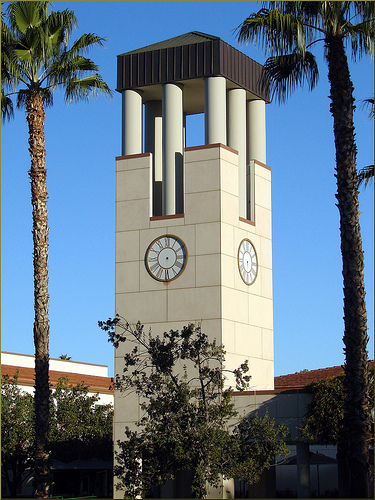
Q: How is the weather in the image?
A: It is clear.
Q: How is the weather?
A: It is clear.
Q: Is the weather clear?
A: Yes, it is clear.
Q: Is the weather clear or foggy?
A: It is clear.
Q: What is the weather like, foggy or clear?
A: It is clear.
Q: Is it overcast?
A: No, it is clear.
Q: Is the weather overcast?
A: No, it is clear.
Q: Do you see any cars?
A: No, there are no cars.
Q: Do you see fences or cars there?
A: No, there are no cars or fences.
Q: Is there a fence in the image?
A: No, there are no fences.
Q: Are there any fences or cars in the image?
A: No, there are no fences or cars.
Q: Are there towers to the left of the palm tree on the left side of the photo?
A: No, the tower is to the right of the palm.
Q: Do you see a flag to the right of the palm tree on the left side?
A: No, there is a tower to the right of the palm tree.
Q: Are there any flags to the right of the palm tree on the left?
A: No, there is a tower to the right of the palm tree.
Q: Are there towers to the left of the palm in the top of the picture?
A: Yes, there is a tower to the left of the palm.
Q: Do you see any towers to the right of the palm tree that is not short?
A: No, the tower is to the left of the palm.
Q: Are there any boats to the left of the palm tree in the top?
A: No, there is a tower to the left of the palm tree.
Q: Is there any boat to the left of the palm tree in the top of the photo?
A: No, there is a tower to the left of the palm tree.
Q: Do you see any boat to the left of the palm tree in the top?
A: No, there is a tower to the left of the palm tree.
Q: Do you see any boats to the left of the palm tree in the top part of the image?
A: No, there is a tower to the left of the palm tree.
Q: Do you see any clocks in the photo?
A: Yes, there is a clock.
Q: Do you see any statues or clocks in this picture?
A: Yes, there is a clock.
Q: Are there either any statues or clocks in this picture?
A: Yes, there is a clock.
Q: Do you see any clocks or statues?
A: Yes, there is a clock.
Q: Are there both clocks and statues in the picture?
A: No, there is a clock but no statues.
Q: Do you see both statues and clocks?
A: No, there is a clock but no statues.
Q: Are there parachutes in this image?
A: No, there are no parachutes.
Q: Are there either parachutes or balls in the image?
A: No, there are no parachutes or balls.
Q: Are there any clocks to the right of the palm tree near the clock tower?
A: Yes, there is a clock to the right of the palm tree.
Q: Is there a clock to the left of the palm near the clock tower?
A: No, the clock is to the right of the palm.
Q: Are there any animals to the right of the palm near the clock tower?
A: No, there is a clock to the right of the palm tree.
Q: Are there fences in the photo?
A: No, there are no fences.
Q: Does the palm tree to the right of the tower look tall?
A: Yes, the palm is tall.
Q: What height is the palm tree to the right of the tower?
A: The palm tree is tall.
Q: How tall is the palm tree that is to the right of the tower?
A: The palm tree is tall.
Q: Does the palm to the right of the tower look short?
A: No, the palm is tall.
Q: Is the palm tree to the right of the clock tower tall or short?
A: The palm is tall.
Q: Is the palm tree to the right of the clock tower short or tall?
A: The palm is tall.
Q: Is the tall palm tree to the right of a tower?
A: Yes, the palm is to the right of a tower.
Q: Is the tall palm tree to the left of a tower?
A: No, the palm is to the right of a tower.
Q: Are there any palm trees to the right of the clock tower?
A: Yes, there is a palm tree to the right of the clock tower.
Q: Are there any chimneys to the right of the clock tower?
A: No, there is a palm tree to the right of the clock tower.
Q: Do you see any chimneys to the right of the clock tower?
A: No, there is a palm tree to the right of the clock tower.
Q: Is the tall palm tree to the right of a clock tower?
A: Yes, the palm is to the right of a clock tower.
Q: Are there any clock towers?
A: Yes, there is a clock tower.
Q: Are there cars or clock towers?
A: Yes, there is a clock tower.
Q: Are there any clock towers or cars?
A: Yes, there is a clock tower.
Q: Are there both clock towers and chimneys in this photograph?
A: No, there is a clock tower but no chimneys.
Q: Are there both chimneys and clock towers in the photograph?
A: No, there is a clock tower but no chimneys.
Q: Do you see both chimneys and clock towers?
A: No, there is a clock tower but no chimneys.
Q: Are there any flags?
A: No, there are no flags.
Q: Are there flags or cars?
A: No, there are no flags or cars.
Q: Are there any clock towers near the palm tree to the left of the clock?
A: Yes, there is a clock tower near the palm tree.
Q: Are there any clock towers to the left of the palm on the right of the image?
A: Yes, there is a clock tower to the left of the palm tree.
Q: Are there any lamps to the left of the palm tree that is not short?
A: No, there is a clock tower to the left of the palm tree.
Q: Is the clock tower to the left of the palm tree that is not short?
A: Yes, the clock tower is to the left of the palm tree.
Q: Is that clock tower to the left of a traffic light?
A: No, the clock tower is to the left of the palm tree.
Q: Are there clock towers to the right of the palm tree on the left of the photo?
A: Yes, there is a clock tower to the right of the palm.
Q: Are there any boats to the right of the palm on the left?
A: No, there is a clock tower to the right of the palm.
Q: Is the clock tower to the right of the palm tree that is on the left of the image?
A: Yes, the clock tower is to the right of the palm tree.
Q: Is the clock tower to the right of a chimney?
A: No, the clock tower is to the right of the palm tree.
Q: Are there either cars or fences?
A: No, there are no cars or fences.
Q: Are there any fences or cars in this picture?
A: No, there are no cars or fences.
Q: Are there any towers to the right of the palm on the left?
A: Yes, there is a tower to the right of the palm.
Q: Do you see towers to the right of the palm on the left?
A: Yes, there is a tower to the right of the palm.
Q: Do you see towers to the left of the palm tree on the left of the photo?
A: No, the tower is to the right of the palm tree.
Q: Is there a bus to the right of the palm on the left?
A: No, there is a tower to the right of the palm tree.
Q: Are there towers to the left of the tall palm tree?
A: Yes, there is a tower to the left of the palm.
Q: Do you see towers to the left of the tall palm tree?
A: Yes, there is a tower to the left of the palm.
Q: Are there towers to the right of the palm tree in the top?
A: No, the tower is to the left of the palm tree.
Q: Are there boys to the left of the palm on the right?
A: No, there is a tower to the left of the palm.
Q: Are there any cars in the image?
A: No, there are no cars.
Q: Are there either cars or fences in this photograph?
A: No, there are no cars or fences.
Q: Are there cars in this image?
A: No, there are no cars.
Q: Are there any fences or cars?
A: No, there are no cars or fences.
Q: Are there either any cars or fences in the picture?
A: No, there are no cars or fences.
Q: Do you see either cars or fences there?
A: No, there are no cars or fences.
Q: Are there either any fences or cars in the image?
A: No, there are no cars or fences.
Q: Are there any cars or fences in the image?
A: No, there are no cars or fences.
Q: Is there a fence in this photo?
A: No, there are no fences.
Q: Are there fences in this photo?
A: No, there are no fences.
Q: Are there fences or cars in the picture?
A: No, there are no fences or cars.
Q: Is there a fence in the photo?
A: No, there are no fences.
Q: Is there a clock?
A: Yes, there is a clock.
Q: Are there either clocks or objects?
A: Yes, there is a clock.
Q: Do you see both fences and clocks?
A: No, there is a clock but no fences.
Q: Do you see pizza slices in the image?
A: No, there are no pizza slices.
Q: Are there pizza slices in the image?
A: No, there are no pizza slices.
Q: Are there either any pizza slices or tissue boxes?
A: No, there are no pizza slices or tissue boxes.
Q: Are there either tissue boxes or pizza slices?
A: No, there are no pizza slices or tissue boxes.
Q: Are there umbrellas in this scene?
A: Yes, there is an umbrella.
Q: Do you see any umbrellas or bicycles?
A: Yes, there is an umbrella.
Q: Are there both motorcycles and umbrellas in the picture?
A: No, there is an umbrella but no motorcycles.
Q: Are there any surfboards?
A: No, there are no surfboards.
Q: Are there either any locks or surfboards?
A: No, there are no surfboards or locks.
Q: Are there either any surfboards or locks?
A: No, there are no surfboards or locks.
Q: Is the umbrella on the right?
A: Yes, the umbrella is on the right of the image.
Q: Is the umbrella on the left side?
A: No, the umbrella is on the right of the image.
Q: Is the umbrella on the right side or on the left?
A: The umbrella is on the right of the image.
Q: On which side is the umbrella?
A: The umbrella is on the right of the image.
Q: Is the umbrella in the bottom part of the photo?
A: Yes, the umbrella is in the bottom of the image.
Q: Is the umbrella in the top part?
A: No, the umbrella is in the bottom of the image.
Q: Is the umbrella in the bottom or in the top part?
A: The umbrella is in the bottom of the image.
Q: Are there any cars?
A: No, there are no cars.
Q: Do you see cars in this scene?
A: No, there are no cars.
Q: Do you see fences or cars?
A: No, there are no cars or fences.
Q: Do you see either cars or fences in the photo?
A: No, there are no cars or fences.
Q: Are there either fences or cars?
A: No, there are no cars or fences.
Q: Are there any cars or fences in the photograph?
A: No, there are no cars or fences.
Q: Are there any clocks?
A: Yes, there is a clock.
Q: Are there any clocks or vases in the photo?
A: Yes, there is a clock.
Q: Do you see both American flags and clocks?
A: No, there is a clock but no American flags.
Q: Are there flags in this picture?
A: No, there are no flags.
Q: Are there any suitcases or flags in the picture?
A: No, there are no flags or suitcases.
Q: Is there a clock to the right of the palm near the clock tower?
A: Yes, there is a clock to the right of the palm.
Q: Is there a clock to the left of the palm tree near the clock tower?
A: No, the clock is to the right of the palm tree.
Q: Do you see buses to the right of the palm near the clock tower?
A: No, there is a clock to the right of the palm tree.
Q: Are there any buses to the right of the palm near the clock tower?
A: No, there is a clock to the right of the palm tree.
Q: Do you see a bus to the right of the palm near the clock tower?
A: No, there is a clock to the right of the palm tree.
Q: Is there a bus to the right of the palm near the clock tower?
A: No, there is a clock to the right of the palm tree.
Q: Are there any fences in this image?
A: No, there are no fences.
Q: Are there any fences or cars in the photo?
A: No, there are no fences or cars.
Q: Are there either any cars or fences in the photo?
A: No, there are no fences or cars.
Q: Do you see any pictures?
A: No, there are no pictures.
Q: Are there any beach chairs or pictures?
A: No, there are no pictures or beach chairs.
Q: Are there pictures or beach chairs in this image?
A: No, there are no pictures or beach chairs.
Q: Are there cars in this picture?
A: No, there are no cars.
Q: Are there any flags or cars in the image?
A: No, there are no cars or flags.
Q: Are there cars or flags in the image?
A: No, there are no cars or flags.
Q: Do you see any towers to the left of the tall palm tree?
A: Yes, there is a tower to the left of the palm tree.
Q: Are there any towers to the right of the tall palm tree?
A: No, the tower is to the left of the palm.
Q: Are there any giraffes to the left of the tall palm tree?
A: No, there is a tower to the left of the palm.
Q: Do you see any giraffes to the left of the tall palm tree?
A: No, there is a tower to the left of the palm.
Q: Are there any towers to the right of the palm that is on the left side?
A: Yes, there is a tower to the right of the palm tree.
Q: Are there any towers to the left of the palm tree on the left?
A: No, the tower is to the right of the palm.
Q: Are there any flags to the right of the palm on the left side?
A: No, there is a tower to the right of the palm tree.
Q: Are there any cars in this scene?
A: No, there are no cars.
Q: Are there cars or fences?
A: No, there are no cars or fences.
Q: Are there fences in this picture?
A: No, there are no fences.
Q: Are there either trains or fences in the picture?
A: No, there are no fences or trains.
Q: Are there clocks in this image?
A: Yes, there is a clock.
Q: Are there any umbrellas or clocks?
A: Yes, there is a clock.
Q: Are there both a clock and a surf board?
A: No, there is a clock but no surfboards.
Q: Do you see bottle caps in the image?
A: No, there are no bottle caps.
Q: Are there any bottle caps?
A: No, there are no bottle caps.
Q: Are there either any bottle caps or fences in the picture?
A: No, there are no bottle caps or fences.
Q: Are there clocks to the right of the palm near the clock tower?
A: Yes, there is a clock to the right of the palm.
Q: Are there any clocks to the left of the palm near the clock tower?
A: No, the clock is to the right of the palm tree.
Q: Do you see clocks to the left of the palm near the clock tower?
A: No, the clock is to the right of the palm tree.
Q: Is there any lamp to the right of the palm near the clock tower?
A: No, there is a clock to the right of the palm.